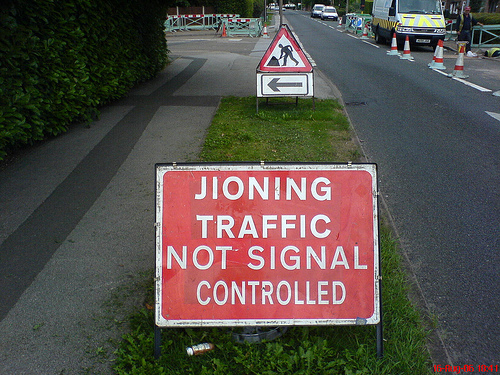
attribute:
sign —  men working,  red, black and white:
[253, 28, 315, 99]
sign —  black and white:
[255, 72, 314, 97]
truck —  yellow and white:
[366, 0, 448, 47]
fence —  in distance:
[168, 11, 240, 28]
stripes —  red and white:
[225, 14, 253, 24]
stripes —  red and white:
[164, 12, 240, 21]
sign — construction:
[248, 26, 328, 118]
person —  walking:
[331, 6, 373, 24]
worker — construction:
[453, 11, 488, 59]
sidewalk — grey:
[8, 50, 205, 363]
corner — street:
[243, 17, 345, 78]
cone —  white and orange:
[361, 21, 373, 47]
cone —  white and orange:
[383, 34, 397, 59]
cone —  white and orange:
[392, 40, 414, 64]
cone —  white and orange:
[430, 41, 448, 70]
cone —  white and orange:
[453, 42, 466, 81]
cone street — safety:
[448, 39, 479, 85]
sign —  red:
[155, 147, 373, 329]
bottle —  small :
[185, 340, 222, 360]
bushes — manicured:
[1, 7, 173, 135]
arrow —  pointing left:
[248, 66, 320, 105]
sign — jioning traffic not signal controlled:
[153, 162, 378, 324]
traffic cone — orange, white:
[448, 45, 468, 80]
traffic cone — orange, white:
[430, 38, 447, 73]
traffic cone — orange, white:
[401, 34, 411, 57]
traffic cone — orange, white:
[388, 30, 396, 56]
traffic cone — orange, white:
[361, 21, 368, 39]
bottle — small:
[183, 338, 216, 357]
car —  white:
[318, 4, 338, 22]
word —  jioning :
[194, 174, 330, 200]